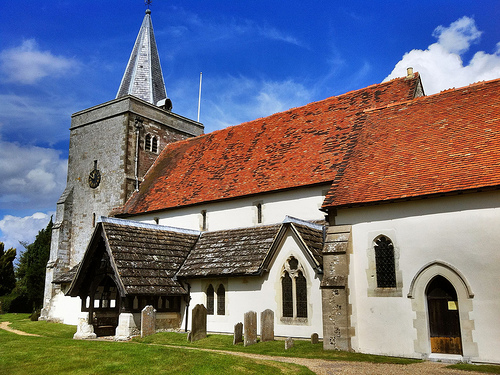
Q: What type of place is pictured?
A: It is a church.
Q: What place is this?
A: It is a church.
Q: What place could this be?
A: It is a church.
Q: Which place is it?
A: It is a church.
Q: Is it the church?
A: Yes, it is the church.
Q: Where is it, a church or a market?
A: It is a church.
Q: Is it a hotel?
A: No, it is a church.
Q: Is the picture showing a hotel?
A: No, the picture is showing a church.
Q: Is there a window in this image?
A: Yes, there is a window.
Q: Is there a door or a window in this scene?
A: Yes, there is a window.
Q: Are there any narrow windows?
A: Yes, there is a narrow window.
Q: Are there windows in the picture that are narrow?
A: Yes, there is a narrow window.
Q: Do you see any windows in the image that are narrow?
A: Yes, there is a window that is narrow.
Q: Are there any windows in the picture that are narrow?
A: Yes, there is a window that is narrow.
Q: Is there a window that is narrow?
A: Yes, there is a window that is narrow.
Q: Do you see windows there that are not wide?
A: Yes, there is a narrow window.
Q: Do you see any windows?
A: Yes, there is a window.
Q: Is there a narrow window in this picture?
A: Yes, there is a narrow window.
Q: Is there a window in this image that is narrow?
A: Yes, there is a window that is narrow.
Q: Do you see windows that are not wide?
A: Yes, there is a narrow window.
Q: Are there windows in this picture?
A: Yes, there is a window.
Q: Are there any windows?
A: Yes, there is a window.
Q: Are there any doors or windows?
A: Yes, there is a window.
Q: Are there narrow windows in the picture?
A: Yes, there is a narrow window.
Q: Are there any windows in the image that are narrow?
A: Yes, there is a window that is narrow.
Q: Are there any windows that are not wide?
A: Yes, there is a narrow window.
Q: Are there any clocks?
A: Yes, there is a clock.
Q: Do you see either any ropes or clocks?
A: Yes, there is a clock.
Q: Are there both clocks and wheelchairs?
A: No, there is a clock but no wheelchairs.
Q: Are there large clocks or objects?
A: Yes, there is a large clock.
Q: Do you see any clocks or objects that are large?
A: Yes, the clock is large.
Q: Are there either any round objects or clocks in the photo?
A: Yes, there is a round clock.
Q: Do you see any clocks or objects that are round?
A: Yes, the clock is round.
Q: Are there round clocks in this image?
A: Yes, there is a round clock.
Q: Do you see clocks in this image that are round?
A: Yes, there is a clock that is round.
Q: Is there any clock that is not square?
A: Yes, there is a round clock.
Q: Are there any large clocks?
A: Yes, there is a large clock.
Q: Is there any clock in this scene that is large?
A: Yes, there is a clock that is large.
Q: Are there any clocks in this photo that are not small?
A: Yes, there is a large clock.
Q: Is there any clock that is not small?
A: Yes, there is a large clock.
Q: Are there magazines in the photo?
A: No, there are no magazines.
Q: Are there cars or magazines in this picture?
A: No, there are no magazines or cars.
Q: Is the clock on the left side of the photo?
A: Yes, the clock is on the left of the image.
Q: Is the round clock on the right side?
A: No, the clock is on the left of the image.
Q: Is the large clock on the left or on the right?
A: The clock is on the left of the image.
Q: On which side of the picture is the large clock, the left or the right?
A: The clock is on the left of the image.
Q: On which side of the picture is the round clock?
A: The clock is on the left of the image.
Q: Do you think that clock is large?
A: Yes, the clock is large.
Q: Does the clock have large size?
A: Yes, the clock is large.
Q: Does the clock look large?
A: Yes, the clock is large.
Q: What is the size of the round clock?
A: The clock is large.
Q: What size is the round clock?
A: The clock is large.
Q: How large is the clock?
A: The clock is large.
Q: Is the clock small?
A: No, the clock is large.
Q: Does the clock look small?
A: No, the clock is large.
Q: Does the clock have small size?
A: No, the clock is large.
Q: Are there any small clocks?
A: No, there is a clock but it is large.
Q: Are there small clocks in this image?
A: No, there is a clock but it is large.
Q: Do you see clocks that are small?
A: No, there is a clock but it is large.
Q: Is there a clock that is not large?
A: No, there is a clock but it is large.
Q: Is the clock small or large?
A: The clock is large.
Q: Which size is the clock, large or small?
A: The clock is large.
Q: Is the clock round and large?
A: Yes, the clock is round and large.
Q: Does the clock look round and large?
A: Yes, the clock is round and large.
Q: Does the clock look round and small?
A: No, the clock is round but large.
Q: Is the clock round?
A: Yes, the clock is round.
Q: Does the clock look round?
A: Yes, the clock is round.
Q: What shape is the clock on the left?
A: The clock is round.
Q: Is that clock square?
A: No, the clock is round.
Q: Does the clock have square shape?
A: No, the clock is round.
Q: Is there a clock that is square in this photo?
A: No, there is a clock but it is round.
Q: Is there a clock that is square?
A: No, there is a clock but it is round.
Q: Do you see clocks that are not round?
A: No, there is a clock but it is round.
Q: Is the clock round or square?
A: The clock is round.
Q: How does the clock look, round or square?
A: The clock is round.